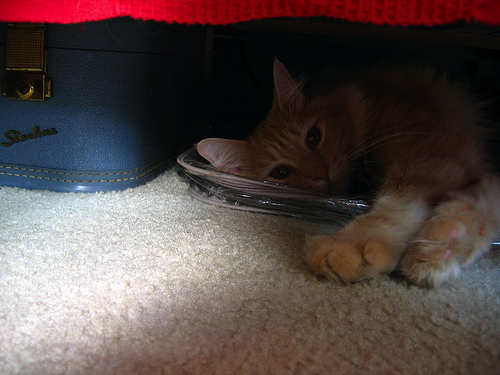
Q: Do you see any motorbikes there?
A: No, there are no motorbikes.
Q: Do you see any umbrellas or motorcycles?
A: No, there are no motorcycles or umbrellas.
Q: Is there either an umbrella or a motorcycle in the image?
A: No, there are no motorcycles or umbrellas.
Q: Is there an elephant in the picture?
A: No, there are no elephants.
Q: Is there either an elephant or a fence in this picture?
A: No, there are no elephants or fences.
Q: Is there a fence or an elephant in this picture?
A: No, there are no elephants or fences.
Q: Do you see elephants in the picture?
A: No, there are no elephants.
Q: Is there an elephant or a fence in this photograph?
A: No, there are no elephants or fences.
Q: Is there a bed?
A: No, there are no beds.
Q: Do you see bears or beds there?
A: No, there are no beds or bears.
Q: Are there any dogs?
A: No, there are no dogs.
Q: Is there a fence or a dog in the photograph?
A: No, there are no dogs or fences.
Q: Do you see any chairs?
A: No, there are no chairs.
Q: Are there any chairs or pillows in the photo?
A: No, there are no chairs or pillows.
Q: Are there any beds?
A: No, there are no beds.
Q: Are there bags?
A: Yes, there is a bag.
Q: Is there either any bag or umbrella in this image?
A: Yes, there is a bag.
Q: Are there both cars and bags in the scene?
A: No, there is a bag but no cars.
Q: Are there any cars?
A: No, there are no cars.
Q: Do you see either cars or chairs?
A: No, there are no cars or chairs.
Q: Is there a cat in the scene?
A: Yes, there is a cat.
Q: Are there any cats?
A: Yes, there is a cat.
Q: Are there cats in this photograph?
A: Yes, there is a cat.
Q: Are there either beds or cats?
A: Yes, there is a cat.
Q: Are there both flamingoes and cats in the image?
A: No, there is a cat but no flamingoes.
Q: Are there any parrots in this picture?
A: No, there are no parrots.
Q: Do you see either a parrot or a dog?
A: No, there are no parrots or dogs.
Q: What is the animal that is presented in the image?
A: The animal is a cat.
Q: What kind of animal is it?
A: The animal is a cat.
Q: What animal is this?
A: That is a cat.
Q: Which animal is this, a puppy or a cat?
A: That is a cat.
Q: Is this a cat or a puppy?
A: This is a cat.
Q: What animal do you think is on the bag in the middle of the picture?
A: The cat is on the bag.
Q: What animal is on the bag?
A: The cat is on the bag.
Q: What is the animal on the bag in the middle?
A: The animal is a cat.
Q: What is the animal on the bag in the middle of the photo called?
A: The animal is a cat.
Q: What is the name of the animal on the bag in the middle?
A: The animal is a cat.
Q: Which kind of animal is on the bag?
A: The animal is a cat.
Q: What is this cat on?
A: The cat is on the bag.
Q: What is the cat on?
A: The cat is on the bag.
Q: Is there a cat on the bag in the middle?
A: Yes, there is a cat on the bag.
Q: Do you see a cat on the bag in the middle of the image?
A: Yes, there is a cat on the bag.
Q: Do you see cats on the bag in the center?
A: Yes, there is a cat on the bag.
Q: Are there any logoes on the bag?
A: No, there is a cat on the bag.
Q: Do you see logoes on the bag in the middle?
A: No, there is a cat on the bag.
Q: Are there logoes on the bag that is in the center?
A: No, there is a cat on the bag.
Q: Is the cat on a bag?
A: Yes, the cat is on a bag.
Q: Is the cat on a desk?
A: No, the cat is on a bag.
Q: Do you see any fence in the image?
A: No, there are no fences.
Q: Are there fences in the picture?
A: No, there are no fences.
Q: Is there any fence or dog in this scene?
A: No, there are no fences or dogs.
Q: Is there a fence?
A: No, there are no fences.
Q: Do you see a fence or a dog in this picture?
A: No, there are no fences or dogs.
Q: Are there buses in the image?
A: No, there are no buses.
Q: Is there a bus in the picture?
A: No, there are no buses.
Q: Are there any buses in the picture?
A: No, there are no buses.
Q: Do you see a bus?
A: No, there are no buses.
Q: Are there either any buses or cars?
A: No, there are no buses or cars.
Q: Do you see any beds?
A: No, there are no beds.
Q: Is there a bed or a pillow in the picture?
A: No, there are no beds or pillows.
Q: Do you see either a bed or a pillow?
A: No, there are no beds or pillows.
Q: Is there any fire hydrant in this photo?
A: No, there are no fire hydrants.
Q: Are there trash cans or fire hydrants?
A: No, there are no fire hydrants or trash cans.